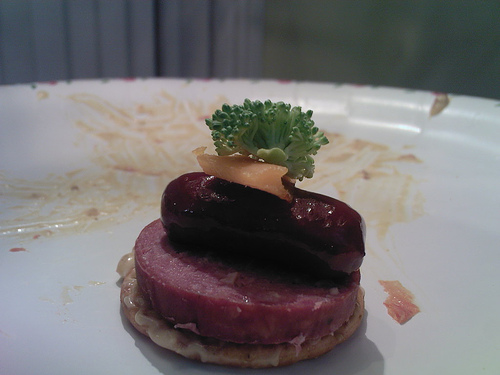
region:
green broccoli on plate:
[228, 97, 308, 179]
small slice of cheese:
[196, 145, 339, 240]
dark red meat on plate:
[146, 167, 366, 280]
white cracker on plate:
[117, 246, 364, 352]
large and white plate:
[72, 60, 496, 339]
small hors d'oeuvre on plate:
[108, 168, 388, 354]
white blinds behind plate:
[22, 12, 208, 73]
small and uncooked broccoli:
[202, 95, 326, 176]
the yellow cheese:
[193, 148, 300, 198]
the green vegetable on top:
[205, 92, 332, 178]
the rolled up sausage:
[159, 171, 366, 291]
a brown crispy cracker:
[116, 255, 367, 370]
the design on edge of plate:
[21, 73, 424, 90]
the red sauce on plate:
[377, 270, 423, 326]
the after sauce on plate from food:
[1, 83, 450, 256]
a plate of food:
[1, 71, 496, 373]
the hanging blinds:
[1, 0, 268, 75]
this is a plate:
[0, 43, 497, 373]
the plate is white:
[0, 43, 499, 360]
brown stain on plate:
[72, 88, 409, 223]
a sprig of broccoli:
[199, 92, 324, 167]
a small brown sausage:
[155, 154, 371, 271]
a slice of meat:
[128, 211, 360, 337]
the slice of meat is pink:
[125, 222, 345, 347]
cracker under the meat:
[117, 263, 386, 372]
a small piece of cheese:
[189, 140, 294, 203]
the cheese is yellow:
[186, 145, 291, 202]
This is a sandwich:
[110, 91, 405, 372]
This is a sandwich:
[262, 188, 381, 312]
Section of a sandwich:
[260, 252, 360, 357]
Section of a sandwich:
[180, 140, 265, 240]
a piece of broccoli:
[199, 81, 329, 181]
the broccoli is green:
[202, 86, 334, 179]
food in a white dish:
[0, 64, 497, 374]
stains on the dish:
[38, 83, 168, 216]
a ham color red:
[148, 168, 373, 290]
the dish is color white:
[0, 63, 499, 371]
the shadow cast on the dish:
[326, 331, 402, 373]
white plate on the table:
[8, 72, 498, 374]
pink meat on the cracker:
[131, 227, 356, 344]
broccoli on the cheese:
[205, 93, 324, 170]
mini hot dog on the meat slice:
[159, 173, 360, 271]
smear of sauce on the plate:
[28, 77, 411, 230]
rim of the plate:
[10, 62, 495, 132]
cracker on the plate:
[110, 268, 367, 364]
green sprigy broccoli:
[207, 99, 324, 169]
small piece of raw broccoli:
[201, 96, 331, 184]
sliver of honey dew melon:
[194, 148, 295, 202]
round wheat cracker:
[118, 249, 365, 366]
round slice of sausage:
[131, 216, 360, 345]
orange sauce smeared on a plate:
[2, 93, 420, 250]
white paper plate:
[0, 74, 497, 373]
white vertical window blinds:
[0, 0, 263, 84]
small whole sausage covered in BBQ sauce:
[162, 169, 367, 286]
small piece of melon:
[378, 276, 418, 322]